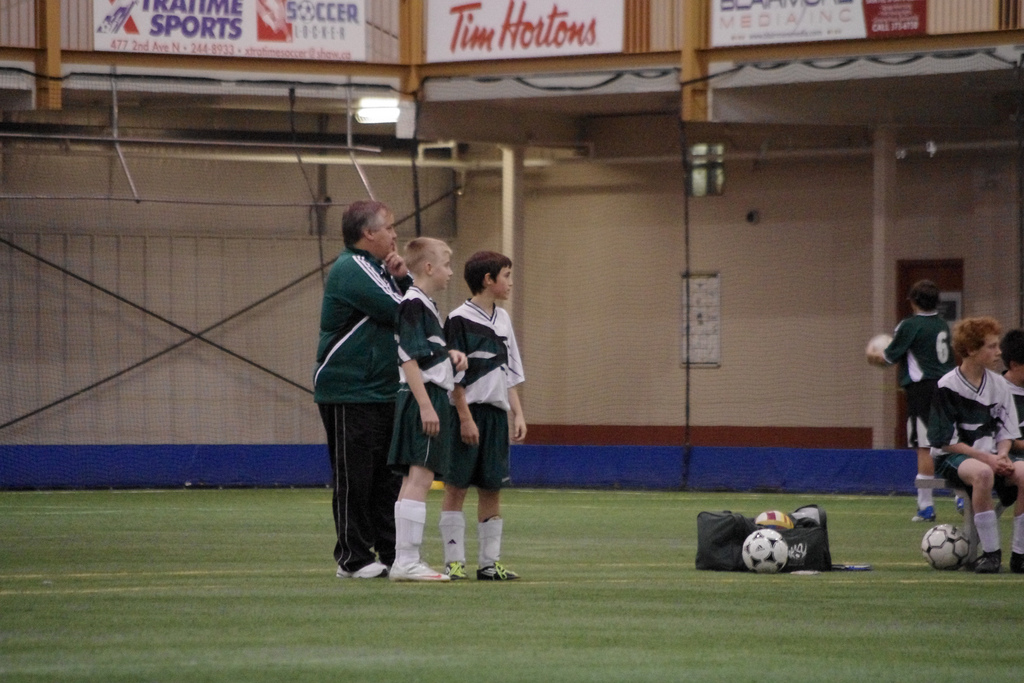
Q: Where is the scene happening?
A: On a soccer field.